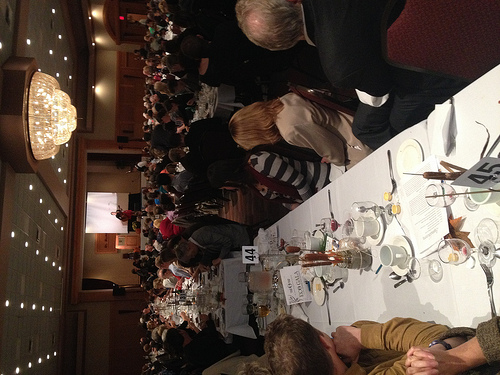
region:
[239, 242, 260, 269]
Table # 44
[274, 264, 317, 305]
Table nameplate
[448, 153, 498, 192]
Table #45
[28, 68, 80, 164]
large glass chandelier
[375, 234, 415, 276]
white coffee cup and saucer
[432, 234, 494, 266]
empty wineglass with small amount of red wine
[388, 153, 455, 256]
conference program/agenda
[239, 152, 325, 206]
black and white striped shirt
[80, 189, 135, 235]
projection screen at the front of the room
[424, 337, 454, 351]
black wristwatch on woman's left arm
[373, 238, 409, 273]
The cup is white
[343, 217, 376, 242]
The cup is white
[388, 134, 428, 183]
The plate is white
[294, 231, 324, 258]
The cup is white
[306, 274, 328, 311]
The plate is white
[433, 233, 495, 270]
The glass is clear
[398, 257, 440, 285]
The glass is clear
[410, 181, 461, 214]
The glass is clear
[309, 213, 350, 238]
The glass is clear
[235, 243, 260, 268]
The numbers are black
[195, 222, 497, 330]
a long white dinner table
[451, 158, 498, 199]
the number forty five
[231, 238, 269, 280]
the number forty four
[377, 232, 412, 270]
a coffee mug on a plate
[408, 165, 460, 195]
a long red candle stick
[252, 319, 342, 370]
the head of an adult male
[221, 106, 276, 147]
the blonde hair of a woman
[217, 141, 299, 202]
the striped shirt of a woman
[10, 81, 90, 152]
a clear white chandelier that is hanging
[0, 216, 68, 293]
a bunch of small lights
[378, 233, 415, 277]
white cup on a saucer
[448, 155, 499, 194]
45 number print on a white sign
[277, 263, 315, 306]
black and white sign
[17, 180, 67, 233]
row of lit ceiling lights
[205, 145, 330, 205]
sitting woman wearing a black and gray top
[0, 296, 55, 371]
two rows of ceiling lights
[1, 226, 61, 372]
three rows of lit ceiling lights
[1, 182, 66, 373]
four lit rows of ceiling lights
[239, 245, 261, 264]
number 44 print on a white sign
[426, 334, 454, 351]
a watch on person's wrist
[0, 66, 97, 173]
the chandelier on the ceiling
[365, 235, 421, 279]
the cup on the table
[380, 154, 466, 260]
the paper on the table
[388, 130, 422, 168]
the saucer under the papers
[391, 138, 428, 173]
the saucer is white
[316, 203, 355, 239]
the glass of wine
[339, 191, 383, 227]
the empty glass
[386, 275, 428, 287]
the spoon on the table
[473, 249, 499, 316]
the fork on the table